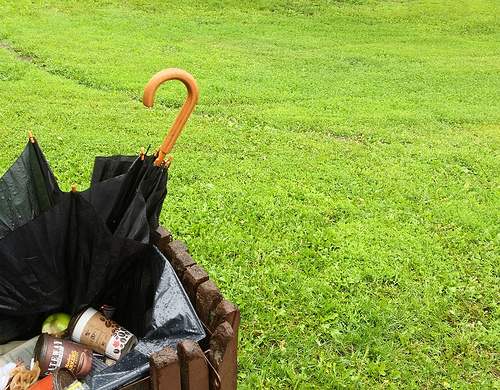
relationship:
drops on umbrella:
[2, 154, 56, 228] [2, 56, 207, 341]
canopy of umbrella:
[6, 130, 176, 326] [2, 56, 207, 341]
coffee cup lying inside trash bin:
[66, 302, 139, 360] [1, 225, 241, 389]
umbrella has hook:
[2, 56, 207, 341] [135, 63, 199, 156]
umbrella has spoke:
[2, 56, 207, 341] [23, 128, 36, 143]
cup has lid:
[22, 366, 76, 389] [50, 364, 77, 389]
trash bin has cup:
[109, 225, 241, 389] [22, 366, 76, 389]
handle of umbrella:
[141, 66, 201, 151] [0, 64, 200, 388]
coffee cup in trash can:
[66, 302, 139, 360] [0, 219, 240, 386]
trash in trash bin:
[2, 303, 144, 388] [1, 225, 241, 389]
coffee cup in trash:
[66, 302, 139, 360] [0, 186, 247, 388]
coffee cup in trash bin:
[66, 302, 139, 360] [1, 225, 241, 389]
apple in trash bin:
[37, 309, 75, 334] [1, 225, 241, 389]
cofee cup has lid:
[28, 332, 100, 381] [30, 328, 57, 369]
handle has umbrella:
[141, 66, 201, 151] [139, 61, 206, 164]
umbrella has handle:
[2, 56, 207, 341] [135, 57, 204, 157]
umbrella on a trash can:
[2, 56, 207, 341] [8, 207, 264, 384]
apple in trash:
[37, 309, 75, 334] [7, 213, 241, 384]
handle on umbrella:
[141, 66, 201, 151] [2, 56, 207, 341]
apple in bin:
[37, 309, 75, 334] [0, 202, 258, 388]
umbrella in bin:
[2, 56, 207, 341] [19, 210, 245, 387]